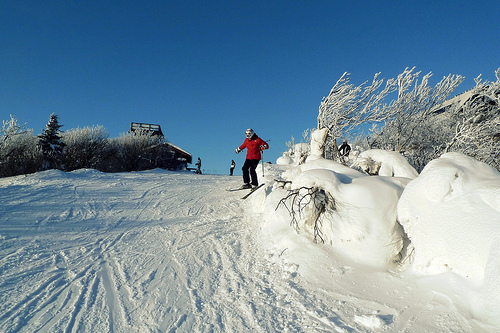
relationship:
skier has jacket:
[226, 122, 273, 198] [240, 137, 272, 160]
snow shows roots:
[1, 169, 498, 332] [276, 183, 339, 248]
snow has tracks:
[1, 169, 498, 332] [2, 220, 144, 331]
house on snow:
[405, 85, 500, 151] [1, 169, 498, 332]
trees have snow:
[319, 67, 391, 156] [332, 79, 355, 106]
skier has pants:
[226, 122, 273, 198] [242, 157, 259, 190]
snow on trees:
[1, 169, 498, 332] [319, 67, 391, 156]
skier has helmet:
[226, 122, 273, 198] [245, 129, 253, 137]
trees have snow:
[319, 67, 391, 156] [1, 169, 498, 332]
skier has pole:
[226, 122, 273, 198] [260, 147, 270, 180]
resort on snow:
[123, 118, 198, 172] [1, 169, 498, 332]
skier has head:
[226, 122, 273, 198] [243, 127, 256, 140]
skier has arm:
[226, 122, 273, 198] [259, 137, 269, 152]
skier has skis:
[226, 122, 273, 198] [226, 181, 268, 201]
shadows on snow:
[0, 164, 172, 234] [1, 169, 498, 332]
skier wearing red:
[226, 122, 273, 198] [240, 137, 272, 160]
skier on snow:
[226, 122, 273, 198] [1, 169, 498, 332]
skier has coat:
[226, 122, 273, 198] [240, 137, 272, 160]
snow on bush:
[69, 128, 163, 164] [65, 142, 162, 168]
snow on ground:
[1, 169, 498, 332] [4, 173, 272, 325]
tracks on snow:
[2, 220, 144, 331] [1, 169, 498, 332]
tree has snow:
[41, 108, 65, 164] [39, 110, 54, 139]